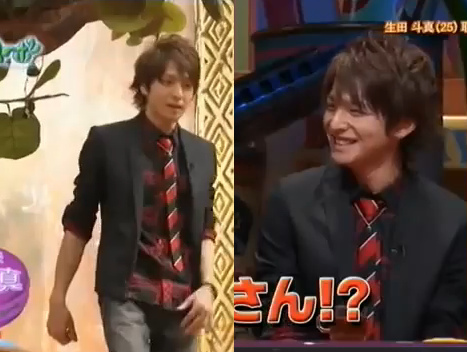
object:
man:
[249, 27, 467, 341]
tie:
[154, 136, 184, 273]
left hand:
[44, 297, 77, 345]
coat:
[61, 111, 217, 312]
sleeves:
[59, 127, 106, 244]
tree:
[0, 62, 71, 160]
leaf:
[0, 100, 42, 161]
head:
[322, 28, 438, 166]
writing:
[228, 273, 371, 323]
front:
[0, 207, 466, 351]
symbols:
[1, 246, 31, 329]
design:
[0, 35, 69, 160]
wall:
[67, 61, 102, 105]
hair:
[344, 48, 409, 84]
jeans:
[97, 295, 194, 351]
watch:
[198, 282, 218, 301]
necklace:
[351, 200, 392, 235]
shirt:
[123, 122, 195, 311]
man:
[44, 32, 218, 352]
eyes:
[159, 77, 173, 87]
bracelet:
[198, 280, 218, 298]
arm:
[48, 126, 103, 303]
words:
[335, 275, 367, 325]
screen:
[0, 0, 467, 352]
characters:
[383, 20, 465, 34]